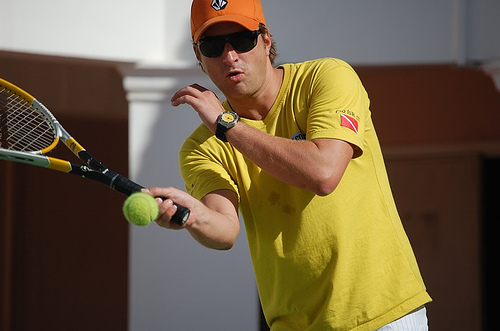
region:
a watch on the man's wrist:
[211, 108, 240, 142]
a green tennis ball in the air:
[121, 187, 159, 229]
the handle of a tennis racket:
[108, 167, 193, 237]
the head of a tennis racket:
[0, 72, 64, 168]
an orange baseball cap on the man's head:
[186, 0, 266, 43]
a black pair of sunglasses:
[188, 25, 270, 60]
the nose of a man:
[220, 40, 238, 65]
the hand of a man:
[168, 81, 227, 136]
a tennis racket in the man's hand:
[0, 72, 197, 231]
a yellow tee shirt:
[174, 55, 437, 330]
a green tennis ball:
[131, 195, 158, 234]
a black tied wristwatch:
[213, 111, 241, 134]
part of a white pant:
[396, 315, 427, 329]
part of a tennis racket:
[6, 101, 111, 193]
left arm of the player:
[249, 136, 314, 198]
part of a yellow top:
[289, 234, 354, 302]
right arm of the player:
[198, 217, 234, 247]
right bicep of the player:
[210, 181, 243, 209]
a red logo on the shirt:
[338, 105, 358, 145]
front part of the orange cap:
[165, 12, 264, 24]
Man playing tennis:
[120, 4, 465, 329]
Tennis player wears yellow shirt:
[128, 0, 450, 327]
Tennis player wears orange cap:
[127, 0, 454, 330]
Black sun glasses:
[185, 25, 270, 58]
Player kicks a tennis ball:
[7, 1, 443, 327]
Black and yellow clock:
[210, 101, 245, 141]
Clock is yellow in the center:
[212, 106, 242, 141]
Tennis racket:
[1, 75, 191, 255]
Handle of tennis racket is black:
[93, 160, 196, 240]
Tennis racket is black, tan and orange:
[2, 74, 198, 236]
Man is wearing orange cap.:
[183, 1, 283, 41]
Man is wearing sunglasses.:
[184, 23, 272, 60]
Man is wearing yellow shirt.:
[161, 53, 431, 327]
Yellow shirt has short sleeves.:
[165, 50, 389, 199]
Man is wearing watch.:
[206, 110, 247, 141]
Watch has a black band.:
[212, 110, 246, 143]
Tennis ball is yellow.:
[118, 182, 165, 231]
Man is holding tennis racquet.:
[0, 72, 198, 229]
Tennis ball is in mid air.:
[111, 190, 163, 227]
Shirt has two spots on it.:
[264, 185, 301, 220]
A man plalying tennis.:
[16, 10, 431, 314]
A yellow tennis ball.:
[118, 185, 162, 232]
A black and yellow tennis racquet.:
[3, 74, 140, 191]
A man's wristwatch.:
[206, 101, 244, 141]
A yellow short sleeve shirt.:
[161, 68, 423, 325]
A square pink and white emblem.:
[328, 112, 365, 132]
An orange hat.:
[186, 4, 271, 35]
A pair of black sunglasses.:
[186, 29, 269, 56]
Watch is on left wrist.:
[186, 77, 281, 157]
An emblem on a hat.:
[205, 0, 238, 15]